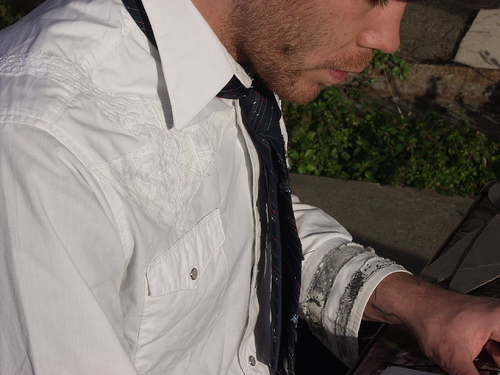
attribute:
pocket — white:
[127, 234, 264, 341]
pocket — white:
[114, 216, 249, 326]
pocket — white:
[124, 212, 240, 322]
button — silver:
[181, 251, 238, 300]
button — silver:
[162, 260, 223, 295]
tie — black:
[224, 101, 333, 362]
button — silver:
[166, 246, 210, 286]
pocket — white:
[150, 208, 233, 337]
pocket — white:
[148, 213, 247, 344]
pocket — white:
[146, 213, 239, 334]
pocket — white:
[156, 199, 231, 352]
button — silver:
[188, 266, 201, 278]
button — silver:
[191, 262, 196, 281]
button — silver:
[184, 265, 200, 283]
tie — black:
[235, 74, 311, 372]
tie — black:
[242, 78, 314, 372]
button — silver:
[188, 257, 210, 286]